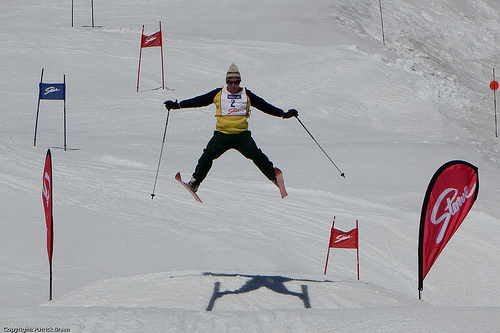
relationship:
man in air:
[161, 53, 304, 208] [11, 6, 499, 329]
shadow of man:
[194, 266, 337, 316] [161, 53, 304, 208]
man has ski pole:
[161, 53, 304, 208] [282, 105, 344, 185]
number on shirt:
[229, 98, 240, 113] [206, 85, 256, 138]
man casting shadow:
[161, 53, 304, 208] [194, 266, 337, 316]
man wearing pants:
[161, 53, 304, 208] [185, 126, 289, 191]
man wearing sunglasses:
[161, 53, 304, 208] [225, 78, 248, 87]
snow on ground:
[341, 3, 495, 120] [11, 6, 499, 329]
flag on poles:
[134, 21, 172, 53] [132, 25, 172, 93]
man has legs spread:
[161, 53, 304, 208] [181, 149, 293, 200]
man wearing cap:
[161, 53, 304, 208] [225, 62, 251, 86]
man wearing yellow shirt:
[161, 53, 304, 208] [206, 85, 256, 138]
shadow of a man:
[194, 266, 337, 316] [161, 53, 304, 208]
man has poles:
[161, 53, 304, 208] [145, 96, 351, 205]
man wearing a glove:
[161, 53, 304, 208] [163, 100, 186, 119]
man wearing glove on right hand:
[161, 53, 304, 208] [163, 100, 186, 119]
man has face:
[161, 53, 304, 208] [223, 78, 243, 93]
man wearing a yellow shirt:
[161, 53, 304, 208] [206, 85, 256, 138]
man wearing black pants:
[161, 53, 304, 208] [185, 126, 289, 191]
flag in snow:
[134, 21, 172, 53] [341, 3, 495, 120]